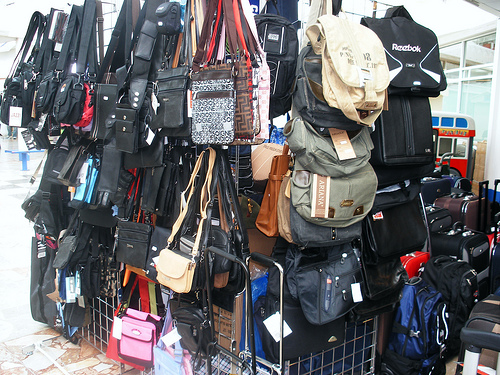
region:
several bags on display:
[3, 1, 490, 374]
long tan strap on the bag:
[154, 149, 224, 251]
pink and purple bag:
[114, 306, 161, 361]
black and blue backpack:
[394, 278, 457, 368]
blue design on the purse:
[193, 81, 235, 143]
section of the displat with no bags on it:
[297, 327, 379, 374]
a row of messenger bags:
[269, 23, 377, 366]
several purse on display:
[0, 1, 261, 374]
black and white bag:
[364, 8, 452, 95]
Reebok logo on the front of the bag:
[387, 38, 427, 55]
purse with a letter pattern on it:
[191, 70, 235, 143]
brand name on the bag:
[392, 43, 422, 51]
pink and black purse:
[118, 307, 160, 363]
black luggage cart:
[200, 246, 252, 373]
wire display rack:
[82, 295, 114, 349]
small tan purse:
[152, 246, 194, 290]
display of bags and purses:
[10, 7, 424, 372]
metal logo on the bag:
[327, 334, 335, 344]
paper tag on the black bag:
[261, 311, 291, 343]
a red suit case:
[402, 250, 430, 280]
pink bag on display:
[118, 306, 163, 368]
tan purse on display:
[153, 143, 217, 294]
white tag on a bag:
[349, 283, 364, 306]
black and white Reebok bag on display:
[360, 3, 448, 94]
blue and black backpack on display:
[388, 258, 458, 373]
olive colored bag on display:
[279, 110, 381, 230]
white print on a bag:
[386, 41, 422, 52]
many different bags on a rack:
[0, 0, 485, 370]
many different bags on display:
[0, 0, 450, 371]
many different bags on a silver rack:
[2, 1, 499, 373]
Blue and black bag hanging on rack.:
[390, 301, 457, 355]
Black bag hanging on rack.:
[434, 253, 455, 314]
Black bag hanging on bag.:
[289, 263, 365, 340]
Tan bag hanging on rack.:
[333, 39, 388, 106]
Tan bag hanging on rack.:
[153, 254, 215, 306]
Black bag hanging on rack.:
[191, 87, 242, 140]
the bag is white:
[310, 16, 397, 136]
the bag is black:
[359, 1, 453, 101]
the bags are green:
[292, 123, 374, 224]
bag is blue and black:
[392, 286, 461, 363]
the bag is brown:
[206, 52, 267, 148]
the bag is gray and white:
[189, 73, 241, 149]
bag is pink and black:
[113, 305, 171, 373]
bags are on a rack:
[5, 6, 430, 373]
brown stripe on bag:
[306, 167, 331, 219]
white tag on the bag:
[262, 308, 307, 352]